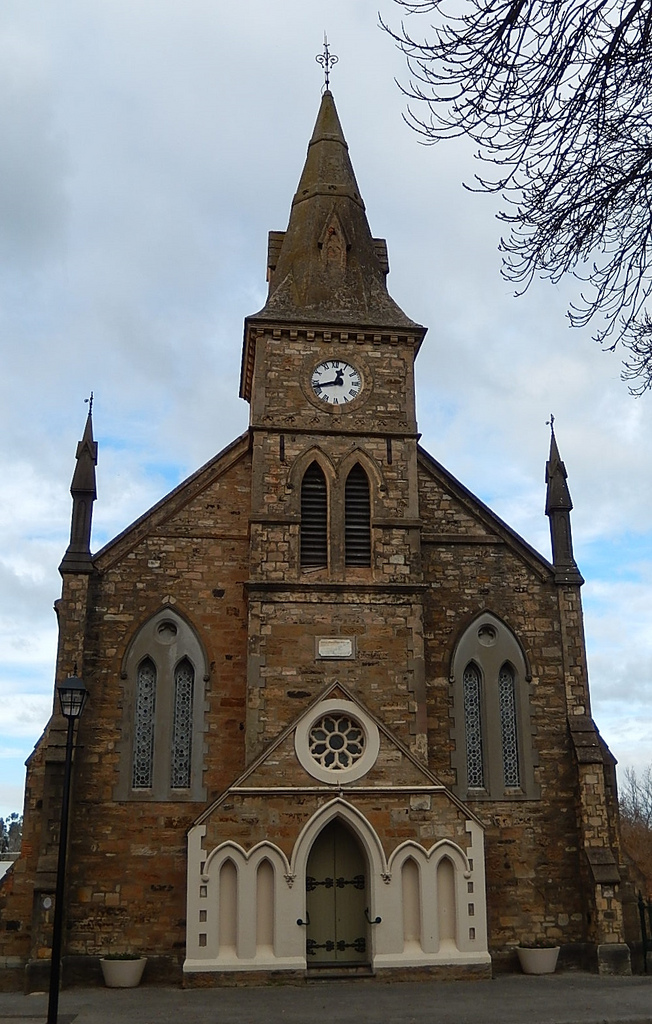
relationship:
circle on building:
[288, 694, 392, 784] [0, 28, 652, 992]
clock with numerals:
[298, 343, 418, 423] [310, 363, 337, 397]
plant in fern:
[98, 935, 150, 956] [99, 952, 148, 988]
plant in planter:
[503, 933, 552, 956] [507, 914, 568, 970]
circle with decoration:
[294, 699, 381, 786] [303, 707, 377, 769]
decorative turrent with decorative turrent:
[507, 396, 612, 558] [545, 413, 575, 567]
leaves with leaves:
[616, 762, 652, 830] [601, 771, 650, 942]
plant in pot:
[104, 952, 141, 961] [98, 939, 140, 1000]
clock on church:
[299, 343, 374, 412] [53, 51, 549, 974]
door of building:
[305, 813, 372, 967] [0, 28, 652, 992]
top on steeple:
[316, 28, 340, 86] [278, 18, 400, 106]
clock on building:
[299, 343, 374, 412] [27, 28, 620, 981]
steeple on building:
[215, 36, 434, 373] [27, 28, 620, 981]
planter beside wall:
[502, 918, 577, 985] [463, 703, 573, 929]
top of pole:
[48, 390, 119, 487] [35, 390, 152, 674]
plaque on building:
[307, 627, 368, 668] [11, 82, 632, 986]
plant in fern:
[104, 952, 141, 961] [99, 952, 148, 988]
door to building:
[305, 813, 372, 967] [27, 28, 620, 981]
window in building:
[450, 614, 529, 803] [27, 28, 620, 981]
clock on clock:
[299, 343, 374, 412] [299, 343, 374, 412]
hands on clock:
[315, 367, 350, 389] [309, 353, 362, 409]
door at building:
[305, 814, 371, 970] [0, 28, 652, 992]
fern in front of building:
[91, 945, 147, 986] [0, 28, 652, 992]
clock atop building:
[299, 343, 374, 412] [0, 28, 652, 992]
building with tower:
[0, 28, 652, 992] [236, 29, 435, 767]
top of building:
[308, 29, 344, 89] [0, 28, 652, 992]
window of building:
[123, 605, 207, 807] [0, 28, 652, 992]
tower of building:
[236, 29, 435, 767] [0, 28, 652, 992]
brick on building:
[262, 541, 289, 551] [11, 82, 632, 986]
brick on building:
[156, 542, 198, 570] [13, 265, 619, 951]